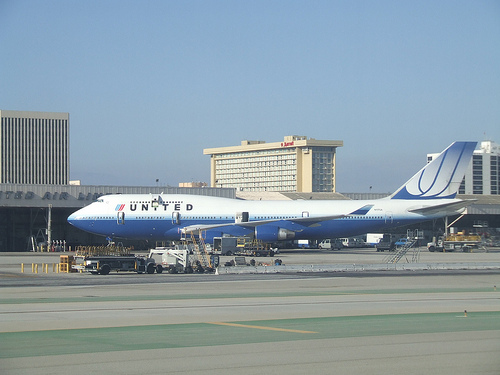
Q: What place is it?
A: It is an airport.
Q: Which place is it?
A: It is an airport.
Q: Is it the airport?
A: Yes, it is the airport.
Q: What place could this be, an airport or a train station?
A: It is an airport.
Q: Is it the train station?
A: No, it is the airport.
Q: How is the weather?
A: It is clear.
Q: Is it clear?
A: Yes, it is clear.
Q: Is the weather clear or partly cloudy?
A: It is clear.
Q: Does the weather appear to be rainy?
A: No, it is clear.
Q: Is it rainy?
A: No, it is clear.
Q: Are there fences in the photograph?
A: No, there are no fences.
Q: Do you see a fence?
A: No, there are no fences.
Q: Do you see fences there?
A: No, there are no fences.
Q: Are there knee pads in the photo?
A: No, there are no knee pads.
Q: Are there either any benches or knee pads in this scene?
A: No, there are no knee pads or benches.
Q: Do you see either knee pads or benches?
A: No, there are no knee pads or benches.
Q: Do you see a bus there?
A: No, there are no buses.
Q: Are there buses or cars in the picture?
A: No, there are no buses or cars.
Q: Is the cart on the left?
A: Yes, the cart is on the left of the image.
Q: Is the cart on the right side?
A: No, the cart is on the left of the image.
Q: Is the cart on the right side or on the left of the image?
A: The cart is on the left of the image.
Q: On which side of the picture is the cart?
A: The cart is on the left of the image.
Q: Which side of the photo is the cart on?
A: The cart is on the left of the image.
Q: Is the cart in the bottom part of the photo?
A: Yes, the cart is in the bottom of the image.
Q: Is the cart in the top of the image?
A: No, the cart is in the bottom of the image.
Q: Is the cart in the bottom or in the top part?
A: The cart is in the bottom of the image.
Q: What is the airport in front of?
A: The airport is in front of the building.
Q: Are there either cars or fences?
A: No, there are no cars or fences.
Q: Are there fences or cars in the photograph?
A: No, there are no cars or fences.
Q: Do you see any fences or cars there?
A: No, there are no cars or fences.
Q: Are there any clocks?
A: No, there are no clocks.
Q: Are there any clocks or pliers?
A: No, there are no clocks or pliers.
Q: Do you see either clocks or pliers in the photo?
A: No, there are no clocks or pliers.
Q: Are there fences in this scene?
A: No, there are no fences.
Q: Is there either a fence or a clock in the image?
A: No, there are no fences or clocks.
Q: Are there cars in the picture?
A: No, there are no cars.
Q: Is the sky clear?
A: Yes, the sky is clear.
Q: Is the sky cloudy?
A: No, the sky is clear.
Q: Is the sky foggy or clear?
A: The sky is clear.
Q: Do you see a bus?
A: No, there are no buses.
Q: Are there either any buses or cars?
A: No, there are no buses or cars.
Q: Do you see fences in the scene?
A: No, there are no fences.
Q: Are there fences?
A: No, there are no fences.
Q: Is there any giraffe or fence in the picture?
A: No, there are no fences or giraffes.